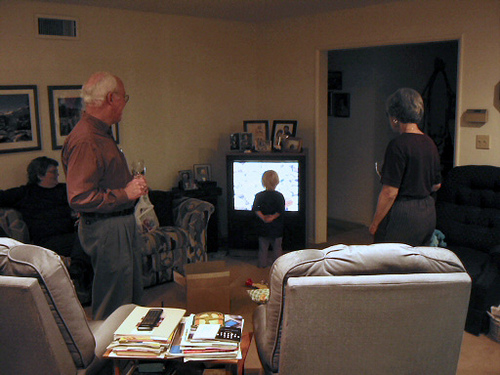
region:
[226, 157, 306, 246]
a large t.v.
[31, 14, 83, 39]
a white ac wall vent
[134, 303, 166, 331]
a long black remote control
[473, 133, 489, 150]
a beige light switch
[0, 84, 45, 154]
part of a picture frame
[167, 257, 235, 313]
an open cardboard box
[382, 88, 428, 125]
a woman's gray hair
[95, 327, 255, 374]
a brown covered table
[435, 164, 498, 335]
part of a black chair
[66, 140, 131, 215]
the arm of a man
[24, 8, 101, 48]
silver and white air vent on wall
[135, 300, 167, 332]
black remote laying on books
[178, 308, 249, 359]
stack of books on table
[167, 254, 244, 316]
brown cardboard box sitting on floor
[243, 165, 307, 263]
child standing in front of television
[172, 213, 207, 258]
design on sofa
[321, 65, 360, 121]
pictures hanging in hallway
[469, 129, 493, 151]
white light switch panel on wall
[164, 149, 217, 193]
pictures sitting on table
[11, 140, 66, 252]
woman in eye glasses sitting on sofa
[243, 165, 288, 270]
the kid is small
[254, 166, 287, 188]
the kid has short hair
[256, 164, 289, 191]
the kid has blonde hair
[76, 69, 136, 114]
the man is balding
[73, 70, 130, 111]
the man has white hair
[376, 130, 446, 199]
the woman is wearing a black shirt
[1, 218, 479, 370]
the chairs are grey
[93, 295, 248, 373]
a stack of magazines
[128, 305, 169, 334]
this is a black remote controler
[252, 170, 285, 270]
Child watches the television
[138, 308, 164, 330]
Remote on paper stack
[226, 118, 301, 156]
Framed pictures sit above the television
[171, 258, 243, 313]
Brown box sits open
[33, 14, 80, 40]
Air vent on the wall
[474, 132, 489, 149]
Light switch on the wall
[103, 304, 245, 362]
Papers stacked on side table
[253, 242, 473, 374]
Large gray chair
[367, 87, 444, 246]
Woman watches the television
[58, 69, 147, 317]
Man watches the television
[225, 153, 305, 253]
black tv boy is standing in front of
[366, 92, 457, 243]
woman standing wearing black outfit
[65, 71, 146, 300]
gray haired man standing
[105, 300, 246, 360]
two stacks of magazines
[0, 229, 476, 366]
two reclining chairs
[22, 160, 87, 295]
woman sitting on couch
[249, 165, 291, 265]
boy standing in front of tv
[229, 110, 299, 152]
picture frames on top of tv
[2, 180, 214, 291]
multi colored couch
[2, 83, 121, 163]
framed pictures above couch